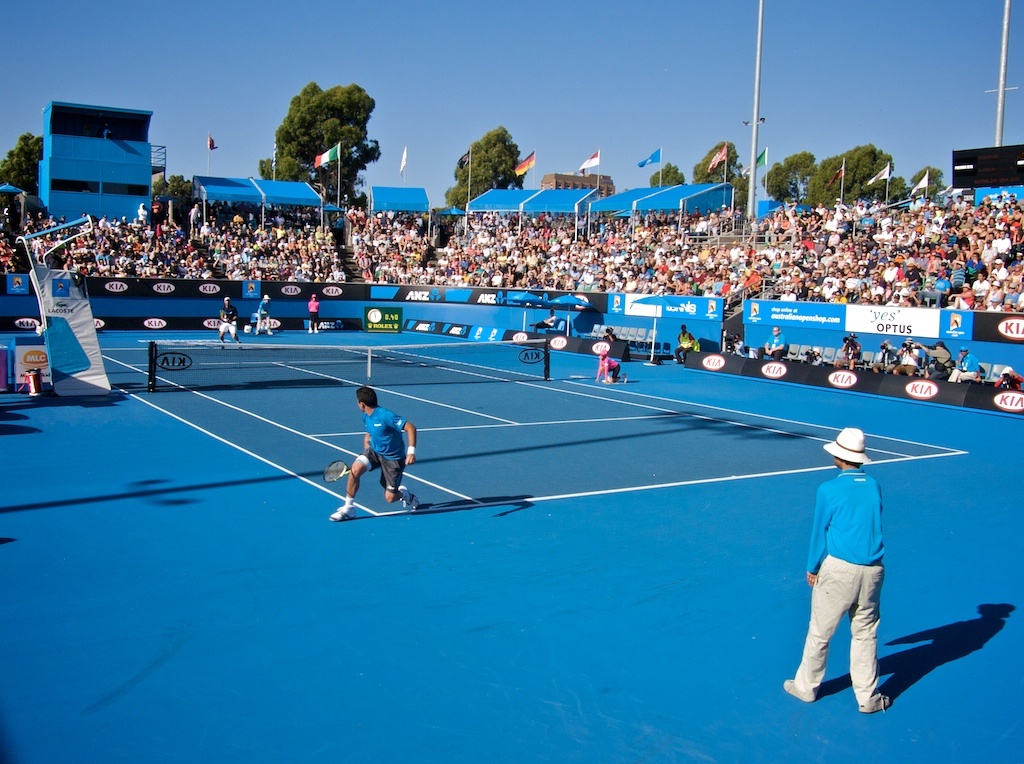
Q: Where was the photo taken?
A: Tennis court.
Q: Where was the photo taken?
A: In a tennis match.